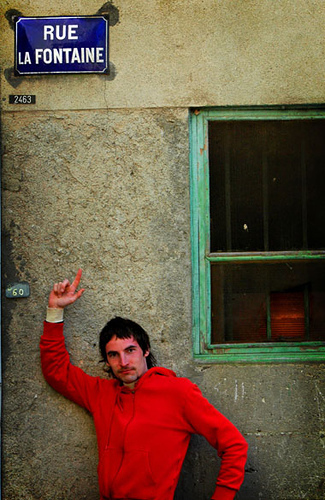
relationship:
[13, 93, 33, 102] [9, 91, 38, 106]
numbers on sign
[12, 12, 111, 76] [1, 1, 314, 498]
sign on building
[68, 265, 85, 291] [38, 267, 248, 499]
finger on man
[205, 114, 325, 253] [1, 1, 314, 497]
window on wall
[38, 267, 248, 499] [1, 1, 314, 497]
man leaning against wall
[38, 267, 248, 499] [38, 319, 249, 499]
man wearing hoodie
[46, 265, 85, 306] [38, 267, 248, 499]
hand on man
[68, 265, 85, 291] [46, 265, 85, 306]
finger on hand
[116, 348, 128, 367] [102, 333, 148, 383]
nose on face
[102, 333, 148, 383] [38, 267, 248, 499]
face on man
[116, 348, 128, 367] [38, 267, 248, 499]
nose on man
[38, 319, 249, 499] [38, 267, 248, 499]
hoodie on man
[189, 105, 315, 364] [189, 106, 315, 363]
frame on window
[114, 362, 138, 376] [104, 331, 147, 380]
mustache on face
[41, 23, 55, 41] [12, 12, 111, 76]
letter on a sign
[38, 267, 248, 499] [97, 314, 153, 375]
man has hair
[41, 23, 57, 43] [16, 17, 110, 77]
letter are on sign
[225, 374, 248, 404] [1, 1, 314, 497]
scratches are on wall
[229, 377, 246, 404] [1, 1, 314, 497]
marks on wall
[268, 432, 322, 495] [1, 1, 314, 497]
scratches on wall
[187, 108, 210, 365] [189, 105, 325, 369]
side board on frame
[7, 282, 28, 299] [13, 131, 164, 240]
number 60 on wall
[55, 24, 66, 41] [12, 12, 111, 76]
letter painted on sign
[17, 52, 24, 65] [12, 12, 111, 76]
letter painted on sign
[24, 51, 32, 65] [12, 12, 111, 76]
letter painted on sign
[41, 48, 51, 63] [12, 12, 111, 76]
letter painted on sign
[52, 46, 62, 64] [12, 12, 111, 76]
letter painted on sign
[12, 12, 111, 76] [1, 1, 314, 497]
sign mounted on wall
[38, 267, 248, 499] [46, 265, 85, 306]
man holding up hand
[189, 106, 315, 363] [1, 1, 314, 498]
window built into building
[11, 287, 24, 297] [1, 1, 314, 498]
number mounted on building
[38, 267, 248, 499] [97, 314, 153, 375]
man growing hair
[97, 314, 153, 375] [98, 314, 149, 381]
hair growing on head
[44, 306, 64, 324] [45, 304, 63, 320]
shirt cuff covering wrist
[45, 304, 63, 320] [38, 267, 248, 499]
wrist belonging to man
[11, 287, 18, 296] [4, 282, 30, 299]
number painted on block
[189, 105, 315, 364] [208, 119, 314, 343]
frame surrounding window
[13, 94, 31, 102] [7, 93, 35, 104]
number painted on block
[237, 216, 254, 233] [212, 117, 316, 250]
mark on top of glass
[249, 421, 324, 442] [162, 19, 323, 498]
crack inside of wall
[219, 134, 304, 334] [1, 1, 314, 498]
bars are inside of building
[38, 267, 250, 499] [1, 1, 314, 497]
man standing against wall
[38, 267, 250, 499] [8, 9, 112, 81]
man pointing to sign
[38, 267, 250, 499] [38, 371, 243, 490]
man wearing jacket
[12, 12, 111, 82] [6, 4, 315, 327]
sign hanging from wall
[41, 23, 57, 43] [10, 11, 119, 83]
letter are printed on sign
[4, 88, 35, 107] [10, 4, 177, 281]
sign hanging on wall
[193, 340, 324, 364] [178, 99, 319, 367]
sill attached to window